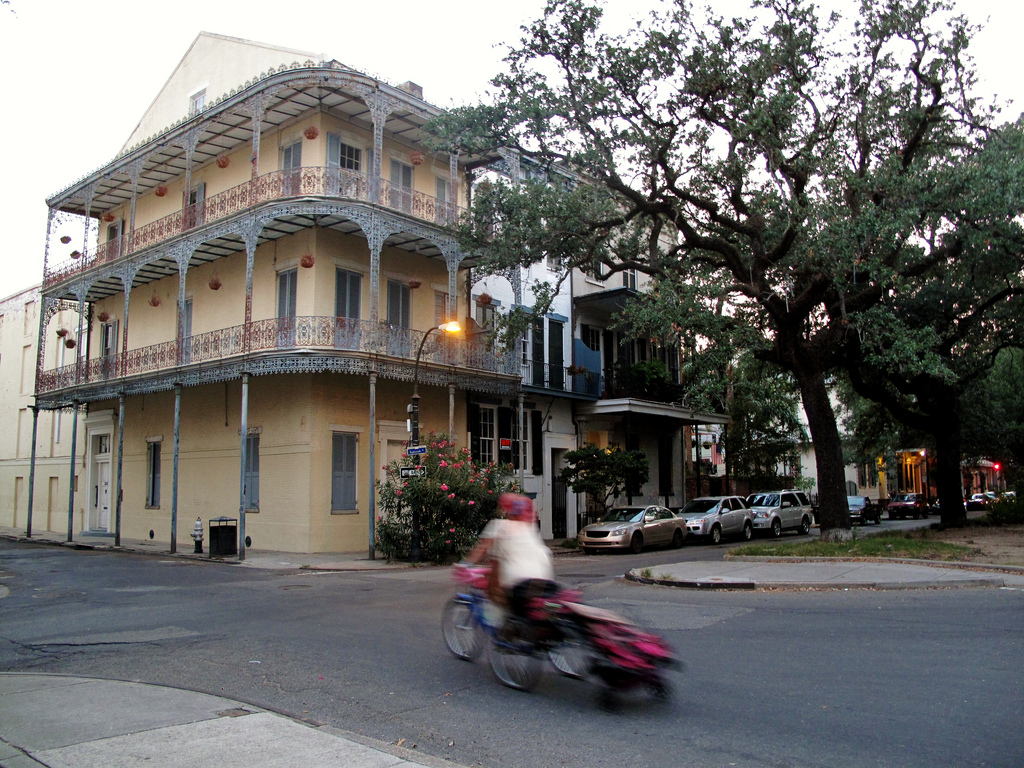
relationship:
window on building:
[136, 437, 175, 518] [8, 44, 739, 574]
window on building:
[172, 279, 194, 362] [8, 44, 739, 574]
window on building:
[272, 262, 305, 347] [8, 44, 739, 574]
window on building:
[377, 268, 438, 346] [8, 44, 739, 574]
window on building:
[423, 275, 476, 368] [8, 44, 739, 574]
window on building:
[337, 133, 383, 211] [8, 44, 739, 574]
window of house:
[265, 137, 330, 196] [52, 22, 504, 573]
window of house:
[267, 266, 307, 336] [39, 163, 515, 565]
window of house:
[267, 266, 307, 336] [52, 22, 504, 573]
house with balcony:
[52, 22, 504, 573] [38, 269, 533, 404]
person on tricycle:
[475, 490, 564, 694] [445, 556, 677, 706]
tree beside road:
[458, 4, 934, 521] [0, 519, 1022, 762]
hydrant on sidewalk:
[188, 516, 204, 551] [10, 531, 847, 575]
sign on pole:
[406, 440, 428, 475] [406, 327, 458, 531]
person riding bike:
[475, 490, 564, 694] [447, 557, 586, 681]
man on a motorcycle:
[454, 480, 558, 645] [445, 558, 672, 706]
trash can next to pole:
[203, 515, 242, 552] [238, 379, 245, 555]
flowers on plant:
[380, 437, 495, 546] [380, 433, 517, 555]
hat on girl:
[495, 487, 534, 520] [473, 485, 554, 641]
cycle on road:
[441, 558, 683, 705] [0, 519, 1022, 762]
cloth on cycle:
[449, 562, 491, 586] [441, 558, 683, 705]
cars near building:
[572, 491, 929, 546] [8, 44, 739, 574]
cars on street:
[577, 485, 1018, 552] [28, 506, 1022, 762]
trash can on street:
[203, 512, 240, 556] [28, 506, 1022, 762]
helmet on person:
[497, 493, 534, 519] [464, 487, 564, 648]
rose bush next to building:
[374, 431, 521, 561] [0, 24, 595, 560]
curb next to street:
[627, 558, 1008, 589] [28, 506, 1022, 762]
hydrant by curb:
[187, 516, 207, 552] [6, 532, 391, 571]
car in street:
[579, 498, 685, 551] [28, 506, 1022, 762]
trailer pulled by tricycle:
[517, 586, 686, 714] [433, 549, 593, 688]